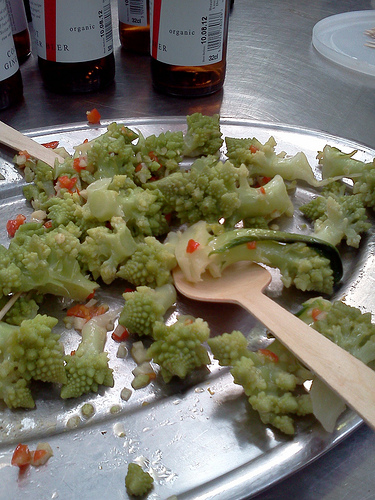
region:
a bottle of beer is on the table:
[147, 0, 231, 101]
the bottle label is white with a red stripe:
[144, 0, 227, 65]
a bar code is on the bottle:
[201, 9, 223, 65]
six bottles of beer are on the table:
[0, 0, 236, 114]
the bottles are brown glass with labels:
[1, 3, 234, 120]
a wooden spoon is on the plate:
[170, 243, 374, 426]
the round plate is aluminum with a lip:
[0, 114, 372, 495]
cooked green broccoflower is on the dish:
[12, 125, 367, 419]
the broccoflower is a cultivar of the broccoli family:
[15, 213, 202, 396]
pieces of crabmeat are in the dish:
[7, 438, 56, 470]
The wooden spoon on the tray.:
[165, 245, 373, 468]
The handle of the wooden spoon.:
[254, 292, 374, 422]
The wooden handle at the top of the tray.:
[1, 119, 60, 171]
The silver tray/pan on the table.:
[9, 269, 372, 496]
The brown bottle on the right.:
[150, 0, 232, 96]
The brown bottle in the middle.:
[28, 2, 122, 90]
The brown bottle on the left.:
[3, 0, 22, 109]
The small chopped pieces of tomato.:
[12, 106, 301, 463]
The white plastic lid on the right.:
[309, 6, 372, 74]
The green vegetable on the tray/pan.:
[18, 106, 331, 484]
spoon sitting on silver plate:
[165, 243, 371, 436]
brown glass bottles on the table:
[1, 5, 235, 109]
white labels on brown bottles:
[1, 4, 215, 76]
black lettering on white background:
[66, 20, 94, 34]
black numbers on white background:
[197, 13, 208, 44]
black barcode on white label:
[206, 13, 222, 61]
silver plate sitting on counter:
[1, 119, 371, 498]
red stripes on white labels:
[38, 3, 160, 64]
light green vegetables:
[7, 127, 369, 429]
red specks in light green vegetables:
[5, 111, 354, 369]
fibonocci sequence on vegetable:
[124, 300, 159, 338]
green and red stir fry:
[13, 122, 339, 385]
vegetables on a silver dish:
[6, 110, 374, 373]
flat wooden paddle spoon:
[162, 223, 374, 433]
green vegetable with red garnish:
[39, 128, 191, 374]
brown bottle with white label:
[145, 0, 228, 96]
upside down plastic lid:
[306, 3, 374, 91]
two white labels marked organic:
[29, 0, 232, 72]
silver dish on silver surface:
[3, 89, 373, 198]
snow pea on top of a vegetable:
[210, 211, 354, 293]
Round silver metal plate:
[6, 114, 369, 497]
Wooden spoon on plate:
[166, 253, 371, 442]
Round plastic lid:
[309, 9, 374, 81]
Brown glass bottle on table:
[143, 0, 239, 100]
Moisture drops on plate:
[107, 384, 225, 484]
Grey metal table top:
[237, 5, 374, 133]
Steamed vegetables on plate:
[7, 107, 369, 434]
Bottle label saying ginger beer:
[25, 36, 73, 56]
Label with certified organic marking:
[165, 25, 199, 39]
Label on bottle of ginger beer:
[139, 1, 227, 69]